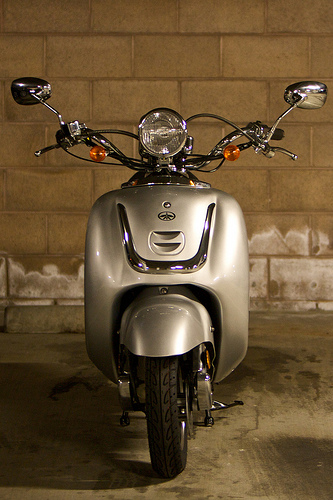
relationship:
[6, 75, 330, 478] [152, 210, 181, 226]
motorcycle has symbol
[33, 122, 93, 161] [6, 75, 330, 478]
handlebar on motorcycle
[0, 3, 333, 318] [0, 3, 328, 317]
cinder blocks of cinder blocks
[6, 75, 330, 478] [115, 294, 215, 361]
scooter has fender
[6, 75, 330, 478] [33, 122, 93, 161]
scooter has handlebar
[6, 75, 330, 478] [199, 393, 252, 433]
motorcycle has kickstand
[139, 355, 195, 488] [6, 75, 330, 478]
tire on moped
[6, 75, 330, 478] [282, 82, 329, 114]
moped has mirror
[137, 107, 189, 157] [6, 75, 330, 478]
headlight on motorcycle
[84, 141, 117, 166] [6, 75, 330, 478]
signal on scooter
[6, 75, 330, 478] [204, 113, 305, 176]
scooter has break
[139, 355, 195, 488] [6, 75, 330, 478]
wheel on scooter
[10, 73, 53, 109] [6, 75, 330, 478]
mirror on motorcycle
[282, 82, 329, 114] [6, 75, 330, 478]
mirror on motorcycle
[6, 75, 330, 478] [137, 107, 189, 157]
scooter has headlight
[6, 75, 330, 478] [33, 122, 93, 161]
motorcycle has handlebar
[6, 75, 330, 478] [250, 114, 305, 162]
motorcycle has handlebar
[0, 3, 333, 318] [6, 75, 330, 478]
cinder blocks behind motorcycle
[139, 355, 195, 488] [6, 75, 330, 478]
wheel on motorcycle